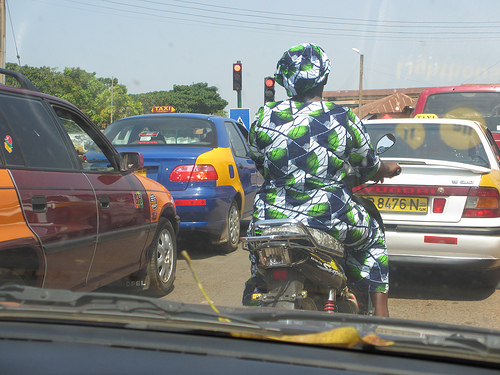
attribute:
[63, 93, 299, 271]
car — blue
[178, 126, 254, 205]
spots — orange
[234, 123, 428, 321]
moped — silver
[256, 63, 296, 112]
light — traffic, red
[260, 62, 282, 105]
semaphore — red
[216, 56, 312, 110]
lights — yellow, red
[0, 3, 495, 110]
sky — daytime, blue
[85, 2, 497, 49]
wires — black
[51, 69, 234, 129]
leaves — green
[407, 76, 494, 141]
truck — red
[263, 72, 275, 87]
circles — glowing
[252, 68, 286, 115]
lights — traffic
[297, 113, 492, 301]
cab — back, taxi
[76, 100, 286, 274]
vehicle — yellow, blue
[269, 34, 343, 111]
head — woman's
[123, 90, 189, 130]
sign — identification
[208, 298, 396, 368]
leaf — dead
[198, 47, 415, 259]
outfit — colorful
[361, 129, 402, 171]
mirror — rearview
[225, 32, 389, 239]
woman — riding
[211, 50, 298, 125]
signals — showing, red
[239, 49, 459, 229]
person — sitting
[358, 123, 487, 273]
car — white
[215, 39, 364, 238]
outfit — blue, green, white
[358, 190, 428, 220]
numbers — black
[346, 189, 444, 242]
plate — yellow, black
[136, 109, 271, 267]
car — blue, yellow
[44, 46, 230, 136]
treetops — peaking